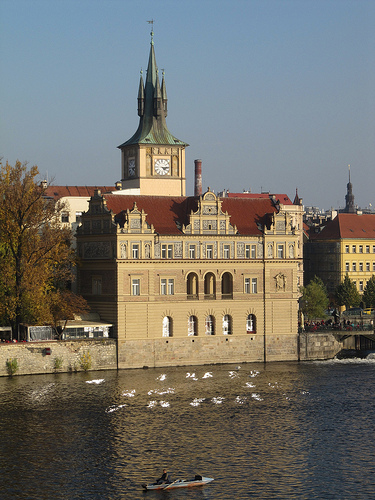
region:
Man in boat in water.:
[137, 455, 242, 494]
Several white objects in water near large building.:
[72, 366, 321, 416]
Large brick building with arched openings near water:
[74, 191, 304, 373]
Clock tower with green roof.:
[114, 44, 194, 194]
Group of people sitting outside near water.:
[296, 308, 373, 341]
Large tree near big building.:
[3, 158, 75, 348]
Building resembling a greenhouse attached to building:
[51, 301, 116, 348]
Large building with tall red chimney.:
[166, 147, 264, 217]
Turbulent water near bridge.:
[296, 332, 372, 379]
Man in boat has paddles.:
[142, 461, 223, 497]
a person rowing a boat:
[144, 473, 213, 489]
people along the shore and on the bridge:
[296, 312, 356, 334]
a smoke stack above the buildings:
[191, 157, 204, 192]